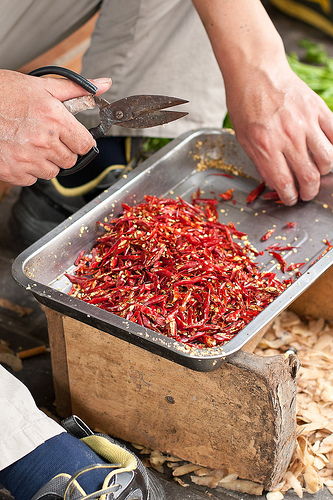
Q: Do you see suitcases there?
A: No, there are no suitcases.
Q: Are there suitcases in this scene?
A: No, there are no suitcases.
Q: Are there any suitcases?
A: No, there are no suitcases.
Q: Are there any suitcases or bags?
A: No, there are no suitcases or bags.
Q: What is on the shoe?
A: The tag is on the shoe.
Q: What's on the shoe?
A: The tag is on the shoe.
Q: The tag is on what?
A: The tag is on the shoe.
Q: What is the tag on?
A: The tag is on the shoe.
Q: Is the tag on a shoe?
A: Yes, the tag is on a shoe.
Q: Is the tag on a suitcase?
A: No, the tag is on a shoe.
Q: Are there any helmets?
A: No, there are no helmets.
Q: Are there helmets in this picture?
A: No, there are no helmets.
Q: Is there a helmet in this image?
A: No, there are no helmets.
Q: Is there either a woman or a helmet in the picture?
A: No, there are no helmets or women.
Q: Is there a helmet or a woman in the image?
A: No, there are no helmets or women.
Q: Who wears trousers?
A: The man wears trousers.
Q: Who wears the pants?
A: The man wears trousers.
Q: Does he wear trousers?
A: Yes, the man wears trousers.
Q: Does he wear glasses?
A: No, the man wears trousers.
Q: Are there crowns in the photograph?
A: No, there are no crowns.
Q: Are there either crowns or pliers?
A: No, there are no crowns or pliers.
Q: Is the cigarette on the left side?
A: Yes, the cigarette is on the left of the image.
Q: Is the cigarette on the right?
A: No, the cigarette is on the left of the image.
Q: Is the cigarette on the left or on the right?
A: The cigarette is on the left of the image.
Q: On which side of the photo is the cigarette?
A: The cigarette is on the left of the image.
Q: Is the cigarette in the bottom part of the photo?
A: Yes, the cigarette is in the bottom of the image.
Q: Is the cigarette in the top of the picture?
A: No, the cigarette is in the bottom of the image.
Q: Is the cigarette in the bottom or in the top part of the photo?
A: The cigarette is in the bottom of the image.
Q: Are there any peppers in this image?
A: Yes, there are peppers.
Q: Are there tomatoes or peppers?
A: Yes, there are peppers.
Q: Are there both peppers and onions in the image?
A: No, there are peppers but no onions.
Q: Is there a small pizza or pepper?
A: Yes, there are small peppers.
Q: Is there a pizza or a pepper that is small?
A: Yes, the peppers are small.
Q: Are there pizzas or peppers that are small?
A: Yes, the peppers are small.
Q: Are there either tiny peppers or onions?
A: Yes, there are tiny peppers.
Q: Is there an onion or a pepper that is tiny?
A: Yes, the peppers are tiny.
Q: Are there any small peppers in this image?
A: Yes, there are small peppers.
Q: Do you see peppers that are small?
A: Yes, there are peppers that are small.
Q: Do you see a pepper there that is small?
A: Yes, there are peppers that are small.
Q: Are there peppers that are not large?
A: Yes, there are small peppers.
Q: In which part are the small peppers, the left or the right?
A: The peppers are on the right of the image.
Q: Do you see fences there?
A: No, there are no fences.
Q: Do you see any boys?
A: No, there are no boys.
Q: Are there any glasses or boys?
A: No, there are no boys or glasses.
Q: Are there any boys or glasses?
A: No, there are no boys or glasses.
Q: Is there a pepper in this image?
A: Yes, there is a pepper.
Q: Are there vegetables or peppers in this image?
A: Yes, there is a pepper.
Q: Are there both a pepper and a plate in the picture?
A: No, there is a pepper but no plates.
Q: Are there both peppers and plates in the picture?
A: No, there is a pepper but no plates.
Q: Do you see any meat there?
A: No, there is no meat.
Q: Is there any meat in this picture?
A: No, there is no meat.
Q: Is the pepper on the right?
A: Yes, the pepper is on the right of the image.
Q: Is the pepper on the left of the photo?
A: No, the pepper is on the right of the image.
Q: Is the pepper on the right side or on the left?
A: The pepper is on the right of the image.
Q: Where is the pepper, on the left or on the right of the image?
A: The pepper is on the right of the image.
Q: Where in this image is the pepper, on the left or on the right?
A: The pepper is on the right of the image.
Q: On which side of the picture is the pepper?
A: The pepper is on the right of the image.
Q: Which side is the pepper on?
A: The pepper is on the right of the image.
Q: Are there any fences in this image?
A: No, there are no fences.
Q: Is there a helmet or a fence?
A: No, there are no fences or helmets.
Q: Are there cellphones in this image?
A: No, there are no cellphones.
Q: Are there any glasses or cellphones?
A: No, there are no cellphones or glasses.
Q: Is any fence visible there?
A: No, there are no fences.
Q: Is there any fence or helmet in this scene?
A: No, there are no fences or helmets.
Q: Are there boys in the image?
A: No, there are no boys.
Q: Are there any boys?
A: No, there are no boys.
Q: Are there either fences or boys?
A: No, there are no boys or fences.